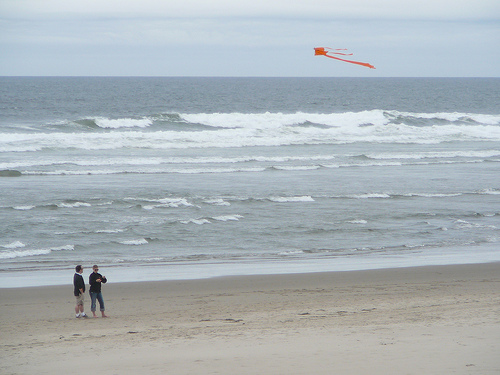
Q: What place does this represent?
A: It represents the ocean.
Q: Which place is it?
A: It is an ocean.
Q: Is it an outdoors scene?
A: Yes, it is outdoors.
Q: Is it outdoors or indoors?
A: It is outdoors.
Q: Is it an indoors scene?
A: No, it is outdoors.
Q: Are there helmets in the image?
A: No, there are no helmets.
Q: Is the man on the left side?
A: Yes, the man is on the left of the image.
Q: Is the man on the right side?
A: No, the man is on the left of the image.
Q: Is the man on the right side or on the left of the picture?
A: The man is on the left of the image.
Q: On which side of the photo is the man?
A: The man is on the left of the image.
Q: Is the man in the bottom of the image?
A: Yes, the man is in the bottom of the image.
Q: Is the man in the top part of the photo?
A: No, the man is in the bottom of the image.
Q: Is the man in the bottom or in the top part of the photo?
A: The man is in the bottom of the image.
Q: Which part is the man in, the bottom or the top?
A: The man is in the bottom of the image.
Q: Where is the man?
A: The man is in the sand.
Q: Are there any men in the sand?
A: Yes, there is a man in the sand.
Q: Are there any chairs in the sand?
A: No, there is a man in the sand.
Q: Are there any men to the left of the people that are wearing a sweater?
A: Yes, there is a man to the left of the people.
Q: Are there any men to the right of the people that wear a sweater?
A: No, the man is to the left of the people.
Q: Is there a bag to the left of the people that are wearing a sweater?
A: No, there is a man to the left of the people.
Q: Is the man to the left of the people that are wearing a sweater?
A: Yes, the man is to the left of the people.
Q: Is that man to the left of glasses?
A: No, the man is to the left of the people.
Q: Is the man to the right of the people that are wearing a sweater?
A: No, the man is to the left of the people.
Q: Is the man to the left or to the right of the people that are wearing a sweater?
A: The man is to the left of the people.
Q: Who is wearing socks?
A: The man is wearing socks.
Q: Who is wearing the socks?
A: The man is wearing socks.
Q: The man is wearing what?
A: The man is wearing socks.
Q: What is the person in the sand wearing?
A: The man is wearing socks.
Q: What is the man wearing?
A: The man is wearing socks.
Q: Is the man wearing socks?
A: Yes, the man is wearing socks.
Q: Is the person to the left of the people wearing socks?
A: Yes, the man is wearing socks.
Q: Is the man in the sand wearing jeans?
A: No, the man is wearing socks.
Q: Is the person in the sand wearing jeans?
A: No, the man is wearing socks.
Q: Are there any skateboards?
A: No, there are no skateboards.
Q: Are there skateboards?
A: No, there are no skateboards.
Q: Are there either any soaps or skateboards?
A: No, there are no skateboards or soaps.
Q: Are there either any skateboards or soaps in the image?
A: No, there are no skateboards or soaps.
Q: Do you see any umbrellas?
A: No, there are no umbrellas.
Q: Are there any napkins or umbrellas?
A: No, there are no umbrellas or napkins.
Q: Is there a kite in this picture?
A: Yes, there is a kite.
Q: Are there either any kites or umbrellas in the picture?
A: Yes, there is a kite.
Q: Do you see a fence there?
A: No, there are no fences.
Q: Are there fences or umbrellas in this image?
A: No, there are no fences or umbrellas.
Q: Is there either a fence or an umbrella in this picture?
A: No, there are no fences or umbrellas.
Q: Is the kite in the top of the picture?
A: Yes, the kite is in the top of the image.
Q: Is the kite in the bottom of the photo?
A: No, the kite is in the top of the image.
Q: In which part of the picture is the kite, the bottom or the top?
A: The kite is in the top of the image.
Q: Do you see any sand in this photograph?
A: Yes, there is sand.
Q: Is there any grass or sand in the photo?
A: Yes, there is sand.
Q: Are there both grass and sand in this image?
A: No, there is sand but no grass.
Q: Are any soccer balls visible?
A: No, there are no soccer balls.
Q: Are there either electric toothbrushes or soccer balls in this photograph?
A: No, there are no soccer balls or electric toothbrushes.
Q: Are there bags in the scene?
A: No, there are no bags.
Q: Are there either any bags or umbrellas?
A: No, there are no bags or umbrellas.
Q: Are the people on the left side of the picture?
A: Yes, the people are on the left of the image.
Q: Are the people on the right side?
A: No, the people are on the left of the image.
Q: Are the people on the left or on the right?
A: The people are on the left of the image.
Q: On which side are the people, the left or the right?
A: The people are on the left of the image.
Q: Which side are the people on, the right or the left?
A: The people are on the left of the image.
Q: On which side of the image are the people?
A: The people are on the left of the image.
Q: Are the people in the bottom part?
A: Yes, the people are in the bottom of the image.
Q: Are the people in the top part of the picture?
A: No, the people are in the bottom of the image.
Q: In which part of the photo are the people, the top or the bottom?
A: The people are in the bottom of the image.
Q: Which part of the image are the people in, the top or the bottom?
A: The people are in the bottom of the image.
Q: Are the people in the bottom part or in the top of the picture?
A: The people are in the bottom of the image.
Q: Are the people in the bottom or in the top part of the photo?
A: The people are in the bottom of the image.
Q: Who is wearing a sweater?
A: The people are wearing a sweater.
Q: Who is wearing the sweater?
A: The people are wearing a sweater.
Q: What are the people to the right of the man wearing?
A: The people are wearing a sweater.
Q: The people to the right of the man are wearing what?
A: The people are wearing a sweater.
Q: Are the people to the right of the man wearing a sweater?
A: Yes, the people are wearing a sweater.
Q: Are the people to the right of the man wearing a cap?
A: No, the people are wearing a sweater.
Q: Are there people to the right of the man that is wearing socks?
A: Yes, there are people to the right of the man.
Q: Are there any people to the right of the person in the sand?
A: Yes, there are people to the right of the man.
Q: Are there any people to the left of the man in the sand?
A: No, the people are to the right of the man.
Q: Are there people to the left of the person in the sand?
A: No, the people are to the right of the man.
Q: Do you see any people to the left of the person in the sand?
A: No, the people are to the right of the man.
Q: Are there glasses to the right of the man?
A: No, there are people to the right of the man.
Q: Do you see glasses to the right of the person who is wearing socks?
A: No, there are people to the right of the man.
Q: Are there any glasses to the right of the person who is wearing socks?
A: No, there are people to the right of the man.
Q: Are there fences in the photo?
A: No, there are no fences.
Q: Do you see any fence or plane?
A: No, there are no fences or airplanes.